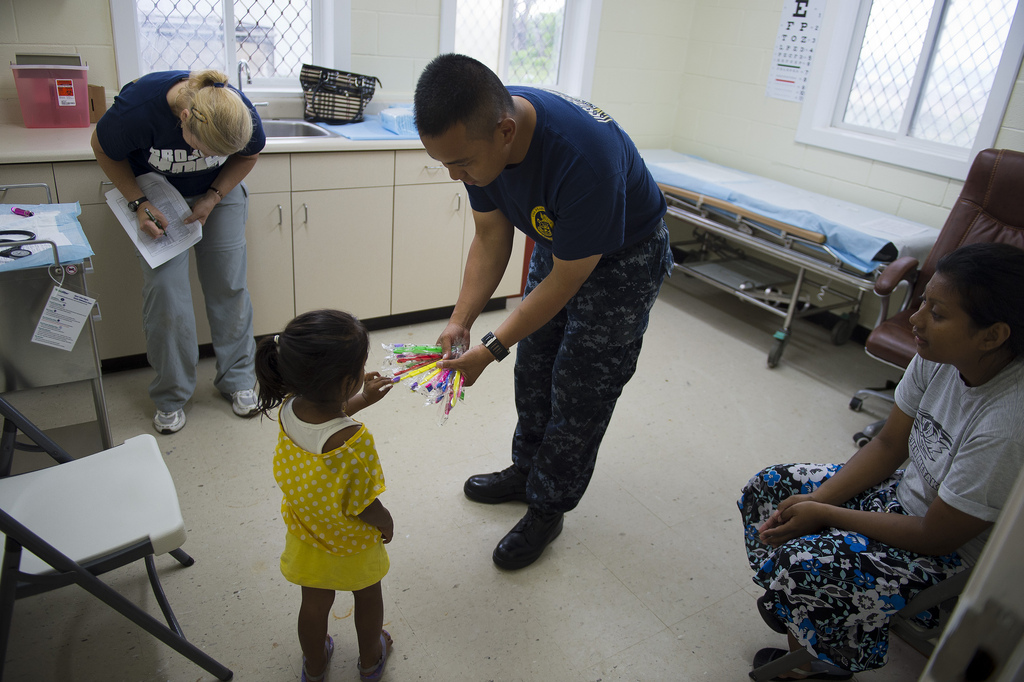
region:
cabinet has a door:
[286, 187, 394, 324]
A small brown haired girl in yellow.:
[253, 307, 393, 681]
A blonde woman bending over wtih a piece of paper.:
[87, 71, 268, 436]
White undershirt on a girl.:
[280, 396, 360, 455]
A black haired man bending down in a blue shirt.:
[409, 52, 673, 574]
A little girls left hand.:
[361, 368, 397, 406]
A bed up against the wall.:
[632, 144, 939, 373]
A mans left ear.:
[498, 116, 519, 146]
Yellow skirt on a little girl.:
[279, 530, 391, 592]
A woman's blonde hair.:
[182, 71, 253, 155]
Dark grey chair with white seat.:
[1, 400, 233, 679]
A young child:
[230, 303, 437, 673]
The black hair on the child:
[242, 304, 372, 402]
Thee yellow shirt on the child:
[249, 431, 398, 549]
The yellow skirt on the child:
[252, 534, 388, 588]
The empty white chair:
[0, 409, 266, 679]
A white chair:
[4, 392, 257, 674]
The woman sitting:
[738, 241, 1015, 674]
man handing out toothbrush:
[392, 52, 681, 607]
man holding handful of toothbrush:
[376, 331, 479, 431]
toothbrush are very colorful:
[371, 317, 479, 420]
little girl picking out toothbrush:
[234, 289, 418, 681]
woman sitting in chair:
[740, 226, 1022, 680]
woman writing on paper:
[88, 163, 228, 293]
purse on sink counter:
[291, 52, 377, 138]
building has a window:
[137, 6, 227, 90]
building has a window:
[232, 2, 310, 91]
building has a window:
[450, 3, 502, 81]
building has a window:
[507, 2, 565, 91]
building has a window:
[842, 0, 937, 137]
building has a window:
[906, 2, 1020, 148]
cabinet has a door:
[287, 186, 398, 327]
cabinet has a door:
[397, 188, 471, 313]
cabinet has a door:
[62, 204, 143, 354]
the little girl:
[254, 310, 401, 680]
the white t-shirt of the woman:
[895, 349, 1020, 528]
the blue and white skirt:
[734, 456, 944, 660]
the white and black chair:
[4, 390, 230, 679]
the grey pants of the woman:
[140, 181, 259, 390]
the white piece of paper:
[106, 174, 205, 267]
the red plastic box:
[8, 64, 94, 131]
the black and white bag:
[296, 63, 380, 127]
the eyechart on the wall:
[768, 3, 825, 102]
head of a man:
[413, 59, 522, 196]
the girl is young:
[258, 303, 395, 668]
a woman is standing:
[95, 65, 266, 413]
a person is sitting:
[743, 249, 1020, 673]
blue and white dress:
[737, 460, 947, 670]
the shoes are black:
[466, 451, 564, 572]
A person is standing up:
[420, 55, 659, 556]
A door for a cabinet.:
[291, 185, 403, 323]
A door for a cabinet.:
[405, 181, 497, 308]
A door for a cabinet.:
[190, 190, 304, 318]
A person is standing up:
[211, 313, 424, 664]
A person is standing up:
[65, 43, 271, 459]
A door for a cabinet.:
[287, 177, 398, 323]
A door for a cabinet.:
[381, 185, 490, 334]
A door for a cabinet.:
[211, 187, 329, 356]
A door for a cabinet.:
[59, 210, 200, 394]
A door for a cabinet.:
[187, 153, 292, 199]